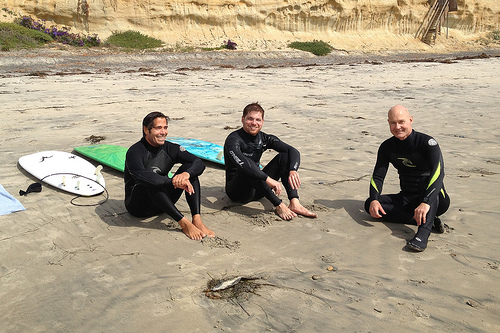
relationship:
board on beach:
[17, 151, 107, 196] [5, 55, 497, 331]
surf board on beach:
[74, 138, 130, 173] [16, 22, 491, 295]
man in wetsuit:
[365, 105, 451, 250] [356, 130, 449, 242]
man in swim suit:
[222, 101, 318, 221] [221, 128, 301, 209]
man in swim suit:
[122, 109, 217, 241] [122, 138, 209, 224]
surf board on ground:
[73, 138, 126, 172] [7, 50, 497, 330]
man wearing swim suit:
[365, 105, 449, 251] [363, 131, 455, 226]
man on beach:
[365, 105, 449, 251] [5, 55, 497, 331]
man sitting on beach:
[222, 98, 320, 233] [5, 55, 497, 331]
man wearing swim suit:
[122, 109, 217, 241] [122, 138, 209, 224]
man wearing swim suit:
[222, 101, 318, 221] [221, 128, 301, 209]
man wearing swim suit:
[365, 105, 451, 250] [362, 128, 452, 253]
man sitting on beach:
[122, 109, 217, 241] [5, 55, 497, 331]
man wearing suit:
[122, 109, 217, 241] [123, 140, 205, 221]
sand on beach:
[59, 237, 126, 283] [5, 55, 497, 331]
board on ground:
[13, 137, 115, 217] [7, 50, 497, 330]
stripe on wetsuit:
[422, 159, 443, 194] [358, 131, 453, 235]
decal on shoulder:
[421, 135, 445, 148] [408, 125, 442, 161]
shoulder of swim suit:
[408, 125, 442, 161] [362, 128, 450, 239]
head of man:
[388, 102, 413, 137] [365, 105, 451, 250]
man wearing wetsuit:
[365, 105, 451, 250] [366, 127, 448, 234]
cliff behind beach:
[103, 8, 270, 66] [236, 37, 408, 132]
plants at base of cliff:
[110, 23, 151, 60] [1, 2, 498, 53]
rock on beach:
[317, 255, 347, 291] [1, 0, 498, 330]